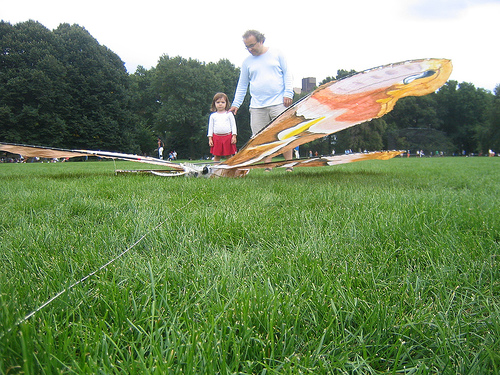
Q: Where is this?
A: This is at the park.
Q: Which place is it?
A: It is a park.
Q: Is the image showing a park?
A: Yes, it is showing a park.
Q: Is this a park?
A: Yes, it is a park.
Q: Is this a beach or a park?
A: It is a park.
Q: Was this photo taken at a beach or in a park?
A: It was taken at a park.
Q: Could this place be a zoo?
A: No, it is a park.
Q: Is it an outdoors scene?
A: Yes, it is outdoors.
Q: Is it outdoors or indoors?
A: It is outdoors.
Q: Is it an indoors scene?
A: No, it is outdoors.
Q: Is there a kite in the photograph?
A: Yes, there is a kite.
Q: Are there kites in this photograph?
A: Yes, there is a kite.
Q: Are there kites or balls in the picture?
A: Yes, there is a kite.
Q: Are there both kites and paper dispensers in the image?
A: No, there is a kite but no paper dispensers.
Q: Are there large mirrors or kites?
A: Yes, there is a large kite.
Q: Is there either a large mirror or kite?
A: Yes, there is a large kite.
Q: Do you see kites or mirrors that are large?
A: Yes, the kite is large.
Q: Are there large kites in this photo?
A: Yes, there is a large kite.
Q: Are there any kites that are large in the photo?
A: Yes, there is a large kite.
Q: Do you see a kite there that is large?
A: Yes, there is a kite that is large.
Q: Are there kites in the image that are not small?
A: Yes, there is a large kite.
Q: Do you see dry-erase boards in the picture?
A: No, there are no dry-erase boards.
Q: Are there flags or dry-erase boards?
A: No, there are no dry-erase boards or flags.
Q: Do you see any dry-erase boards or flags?
A: No, there are no dry-erase boards or flags.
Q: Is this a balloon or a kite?
A: This is a kite.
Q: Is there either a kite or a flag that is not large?
A: No, there is a kite but it is large.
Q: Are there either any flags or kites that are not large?
A: No, there is a kite but it is large.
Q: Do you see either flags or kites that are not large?
A: No, there is a kite but it is large.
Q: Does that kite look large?
A: Yes, the kite is large.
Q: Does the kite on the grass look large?
A: Yes, the kite is large.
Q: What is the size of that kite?
A: The kite is large.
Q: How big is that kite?
A: The kite is large.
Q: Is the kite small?
A: No, the kite is large.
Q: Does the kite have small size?
A: No, the kite is large.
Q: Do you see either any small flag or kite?
A: No, there is a kite but it is large.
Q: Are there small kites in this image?
A: No, there is a kite but it is large.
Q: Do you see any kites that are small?
A: No, there is a kite but it is large.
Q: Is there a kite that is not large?
A: No, there is a kite but it is large.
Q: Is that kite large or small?
A: The kite is large.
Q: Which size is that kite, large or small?
A: The kite is large.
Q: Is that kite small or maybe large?
A: The kite is large.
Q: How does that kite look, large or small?
A: The kite is large.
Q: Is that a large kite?
A: Yes, that is a large kite.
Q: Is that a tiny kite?
A: No, that is a large kite.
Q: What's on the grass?
A: The kite is on the grass.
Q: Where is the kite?
A: The kite is on the grass.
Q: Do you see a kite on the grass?
A: Yes, there is a kite on the grass.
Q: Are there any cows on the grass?
A: No, there is a kite on the grass.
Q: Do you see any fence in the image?
A: No, there are no fences.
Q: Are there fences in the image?
A: No, there are no fences.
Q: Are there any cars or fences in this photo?
A: No, there are no fences or cars.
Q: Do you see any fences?
A: No, there are no fences.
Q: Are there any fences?
A: No, there are no fences.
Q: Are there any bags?
A: No, there are no bags.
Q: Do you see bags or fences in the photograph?
A: No, there are no bags or fences.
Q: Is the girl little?
A: Yes, the girl is little.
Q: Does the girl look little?
A: Yes, the girl is little.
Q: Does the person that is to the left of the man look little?
A: Yes, the girl is little.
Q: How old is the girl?
A: The girl is little.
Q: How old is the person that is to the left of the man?
A: The girl is little.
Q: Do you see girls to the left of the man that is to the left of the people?
A: Yes, there is a girl to the left of the man.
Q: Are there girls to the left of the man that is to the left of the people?
A: Yes, there is a girl to the left of the man.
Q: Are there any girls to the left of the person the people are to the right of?
A: Yes, there is a girl to the left of the man.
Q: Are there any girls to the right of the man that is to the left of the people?
A: No, the girl is to the left of the man.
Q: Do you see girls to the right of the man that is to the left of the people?
A: No, the girl is to the left of the man.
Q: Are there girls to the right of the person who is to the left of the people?
A: No, the girl is to the left of the man.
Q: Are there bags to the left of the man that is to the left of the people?
A: No, there is a girl to the left of the man.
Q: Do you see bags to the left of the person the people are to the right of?
A: No, there is a girl to the left of the man.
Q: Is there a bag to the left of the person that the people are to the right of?
A: No, there is a girl to the left of the man.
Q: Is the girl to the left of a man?
A: Yes, the girl is to the left of a man.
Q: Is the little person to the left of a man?
A: Yes, the girl is to the left of a man.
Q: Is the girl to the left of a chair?
A: No, the girl is to the left of a man.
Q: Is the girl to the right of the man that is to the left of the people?
A: No, the girl is to the left of the man.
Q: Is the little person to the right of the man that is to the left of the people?
A: No, the girl is to the left of the man.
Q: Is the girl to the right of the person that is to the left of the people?
A: No, the girl is to the left of the man.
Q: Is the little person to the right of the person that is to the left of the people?
A: No, the girl is to the left of the man.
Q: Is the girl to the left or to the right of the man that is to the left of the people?
A: The girl is to the left of the man.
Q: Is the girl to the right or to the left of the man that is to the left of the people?
A: The girl is to the left of the man.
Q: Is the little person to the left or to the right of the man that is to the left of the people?
A: The girl is to the left of the man.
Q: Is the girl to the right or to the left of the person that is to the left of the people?
A: The girl is to the left of the man.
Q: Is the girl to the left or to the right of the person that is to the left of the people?
A: The girl is to the left of the man.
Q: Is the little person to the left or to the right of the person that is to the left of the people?
A: The girl is to the left of the man.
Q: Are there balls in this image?
A: No, there are no balls.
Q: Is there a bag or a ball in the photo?
A: No, there are no balls or bags.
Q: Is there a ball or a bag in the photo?
A: No, there are no balls or bags.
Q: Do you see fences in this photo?
A: No, there are no fences.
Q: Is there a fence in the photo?
A: No, there are no fences.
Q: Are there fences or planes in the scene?
A: No, there are no fences or planes.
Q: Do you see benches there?
A: No, there are no benches.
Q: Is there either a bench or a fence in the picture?
A: No, there are no benches or fences.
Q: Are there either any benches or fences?
A: No, there are no benches or fences.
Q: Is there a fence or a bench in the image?
A: No, there are no benches or fences.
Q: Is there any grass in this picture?
A: Yes, there is grass.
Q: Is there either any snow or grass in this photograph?
A: Yes, there is grass.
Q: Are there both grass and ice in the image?
A: No, there is grass but no ice.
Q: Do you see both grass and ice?
A: No, there is grass but no ice.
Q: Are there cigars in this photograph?
A: No, there are no cigars.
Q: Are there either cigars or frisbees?
A: No, there are no cigars or frisbees.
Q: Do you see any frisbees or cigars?
A: No, there are no cigars or frisbees.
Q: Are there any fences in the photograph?
A: No, there are no fences.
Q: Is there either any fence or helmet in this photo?
A: No, there are no fences or helmets.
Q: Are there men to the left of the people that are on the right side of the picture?
A: Yes, there is a man to the left of the people.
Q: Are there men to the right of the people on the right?
A: No, the man is to the left of the people.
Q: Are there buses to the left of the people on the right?
A: No, there is a man to the left of the people.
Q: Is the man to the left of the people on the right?
A: Yes, the man is to the left of the people.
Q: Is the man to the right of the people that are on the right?
A: No, the man is to the left of the people.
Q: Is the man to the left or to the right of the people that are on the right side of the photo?
A: The man is to the left of the people.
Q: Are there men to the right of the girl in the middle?
A: Yes, there is a man to the right of the girl.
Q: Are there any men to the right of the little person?
A: Yes, there is a man to the right of the girl.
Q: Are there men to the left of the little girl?
A: No, the man is to the right of the girl.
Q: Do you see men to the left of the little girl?
A: No, the man is to the right of the girl.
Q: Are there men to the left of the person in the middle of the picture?
A: No, the man is to the right of the girl.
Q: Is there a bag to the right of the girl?
A: No, there is a man to the right of the girl.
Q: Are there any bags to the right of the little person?
A: No, there is a man to the right of the girl.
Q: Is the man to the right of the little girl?
A: Yes, the man is to the right of the girl.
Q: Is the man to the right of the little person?
A: Yes, the man is to the right of the girl.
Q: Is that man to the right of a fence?
A: No, the man is to the right of the girl.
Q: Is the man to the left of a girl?
A: No, the man is to the right of a girl.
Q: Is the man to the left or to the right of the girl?
A: The man is to the right of the girl.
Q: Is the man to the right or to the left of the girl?
A: The man is to the right of the girl.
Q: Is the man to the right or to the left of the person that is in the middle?
A: The man is to the right of the girl.